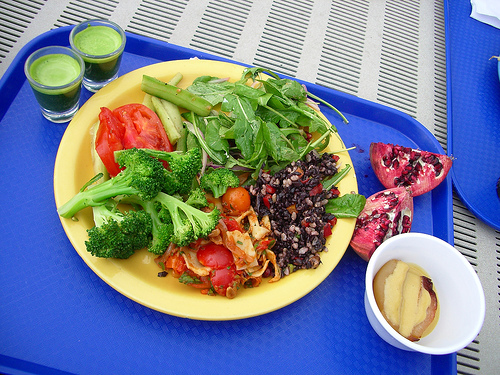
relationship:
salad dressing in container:
[73, 26, 122, 85] [68, 19, 126, 92]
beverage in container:
[27, 52, 82, 114] [25, 44, 83, 123]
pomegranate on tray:
[371, 140, 453, 195] [1, 23, 457, 373]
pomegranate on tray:
[350, 184, 412, 261] [1, 23, 457, 373]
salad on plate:
[56, 66, 366, 299] [51, 58, 358, 322]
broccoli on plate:
[56, 147, 239, 257] [51, 58, 358, 322]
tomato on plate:
[95, 102, 175, 177] [51, 58, 358, 322]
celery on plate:
[138, 72, 212, 142] [51, 58, 358, 322]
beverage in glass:
[29, 55, 81, 114] [23, 44, 86, 124]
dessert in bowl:
[371, 258, 437, 342] [363, 230, 483, 353]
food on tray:
[56, 64, 456, 341] [1, 23, 457, 373]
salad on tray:
[56, 66, 366, 297] [1, 23, 457, 373]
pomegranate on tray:
[368, 140, 453, 195] [24, 20, 439, 369]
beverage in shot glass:
[27, 52, 82, 114] [24, 44, 87, 133]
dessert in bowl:
[380, 256, 443, 344] [363, 230, 483, 353]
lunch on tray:
[42, 34, 469, 344] [1, 23, 457, 373]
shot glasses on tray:
[25, 12, 132, 114] [1, 23, 457, 373]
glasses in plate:
[24, 19, 127, 124] [15, 23, 449, 373]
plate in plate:
[64, 75, 337, 309] [15, 23, 449, 373]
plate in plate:
[51, 58, 358, 322] [15, 23, 449, 373]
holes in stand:
[259, 25, 300, 60] [28, 7, 439, 67]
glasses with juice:
[35, 23, 128, 114] [34, 27, 129, 104]